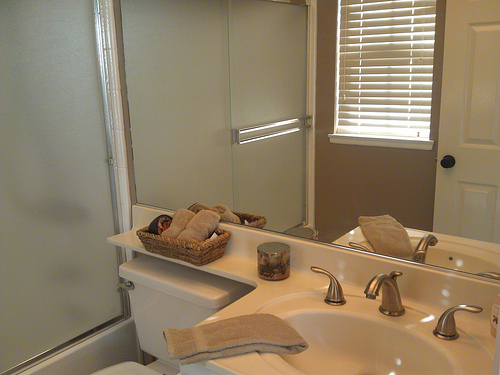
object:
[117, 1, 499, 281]
mirror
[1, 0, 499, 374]
bathroom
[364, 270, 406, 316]
faucet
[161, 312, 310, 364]
hand towel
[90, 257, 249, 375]
toilet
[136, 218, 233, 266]
basket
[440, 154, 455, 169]
door knob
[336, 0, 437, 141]
window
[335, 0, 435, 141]
shutters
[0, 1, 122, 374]
shower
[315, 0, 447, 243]
reflection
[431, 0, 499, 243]
door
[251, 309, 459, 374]
sink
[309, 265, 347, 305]
handle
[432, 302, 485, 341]
handle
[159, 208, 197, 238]
towel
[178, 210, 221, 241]
towel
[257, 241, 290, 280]
candle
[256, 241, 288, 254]
top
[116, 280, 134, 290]
lever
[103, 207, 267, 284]
shelf